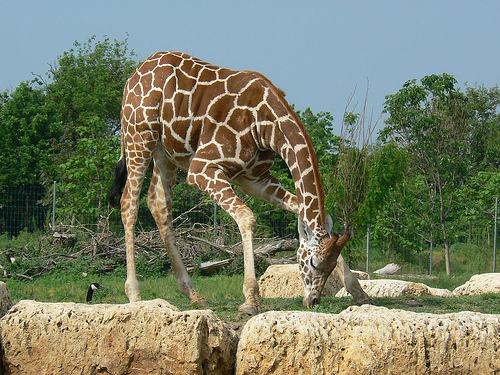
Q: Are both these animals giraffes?
A: No, they are giraffes and birds.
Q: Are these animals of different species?
A: Yes, they are giraffes and birds.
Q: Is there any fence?
A: Yes, there is a fence.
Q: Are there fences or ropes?
A: Yes, there is a fence.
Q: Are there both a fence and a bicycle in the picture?
A: No, there is a fence but no bicycles.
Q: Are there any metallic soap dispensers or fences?
A: Yes, there is a metal fence.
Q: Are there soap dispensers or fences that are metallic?
A: Yes, the fence is metallic.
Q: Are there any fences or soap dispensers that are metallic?
A: Yes, the fence is metallic.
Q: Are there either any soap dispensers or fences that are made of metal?
A: Yes, the fence is made of metal.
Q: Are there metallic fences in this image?
A: Yes, there is a metal fence.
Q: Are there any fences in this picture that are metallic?
A: Yes, there is a fence that is metallic.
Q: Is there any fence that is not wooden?
A: Yes, there is a metallic fence.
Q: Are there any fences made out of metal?
A: Yes, there is a fence that is made of metal.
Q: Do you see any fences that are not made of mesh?
A: Yes, there is a fence that is made of metal.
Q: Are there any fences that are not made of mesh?
A: Yes, there is a fence that is made of metal.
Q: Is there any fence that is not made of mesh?
A: Yes, there is a fence that is made of metal.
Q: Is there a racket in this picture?
A: No, there are no rackets.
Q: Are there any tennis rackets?
A: No, there are no tennis rackets.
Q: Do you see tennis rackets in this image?
A: No, there are no tennis rackets.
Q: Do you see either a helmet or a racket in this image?
A: No, there are no rackets or helmets.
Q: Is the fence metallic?
A: Yes, the fence is metallic.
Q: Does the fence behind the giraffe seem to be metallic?
A: Yes, the fence is metallic.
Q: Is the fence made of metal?
A: Yes, the fence is made of metal.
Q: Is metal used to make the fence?
A: Yes, the fence is made of metal.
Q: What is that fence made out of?
A: The fence is made of metal.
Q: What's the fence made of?
A: The fence is made of metal.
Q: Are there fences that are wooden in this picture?
A: No, there is a fence but it is metallic.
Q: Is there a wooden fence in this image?
A: No, there is a fence but it is metallic.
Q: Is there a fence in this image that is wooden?
A: No, there is a fence but it is metallic.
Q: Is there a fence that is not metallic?
A: No, there is a fence but it is metallic.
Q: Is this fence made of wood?
A: No, the fence is made of metal.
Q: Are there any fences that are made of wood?
A: No, there is a fence but it is made of metal.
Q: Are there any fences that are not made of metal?
A: No, there is a fence but it is made of metal.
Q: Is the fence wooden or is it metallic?
A: The fence is metallic.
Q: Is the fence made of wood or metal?
A: The fence is made of metal.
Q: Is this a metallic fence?
A: Yes, this is a metallic fence.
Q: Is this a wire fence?
A: No, this is a metallic fence.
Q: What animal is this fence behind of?
A: The fence is behind the giraffe.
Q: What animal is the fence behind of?
A: The fence is behind the giraffe.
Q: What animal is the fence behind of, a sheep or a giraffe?
A: The fence is behind a giraffe.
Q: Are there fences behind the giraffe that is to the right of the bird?
A: Yes, there is a fence behind the giraffe.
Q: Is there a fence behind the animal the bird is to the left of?
A: Yes, there is a fence behind the giraffe.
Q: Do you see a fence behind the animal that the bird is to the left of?
A: Yes, there is a fence behind the giraffe.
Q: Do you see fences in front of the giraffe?
A: No, the fence is behind the giraffe.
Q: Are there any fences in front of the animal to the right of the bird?
A: No, the fence is behind the giraffe.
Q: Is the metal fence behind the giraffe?
A: Yes, the fence is behind the giraffe.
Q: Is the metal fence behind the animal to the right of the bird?
A: Yes, the fence is behind the giraffe.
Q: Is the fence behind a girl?
A: No, the fence is behind the giraffe.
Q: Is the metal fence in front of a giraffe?
A: No, the fence is behind a giraffe.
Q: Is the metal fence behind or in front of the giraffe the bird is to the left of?
A: The fence is behind the giraffe.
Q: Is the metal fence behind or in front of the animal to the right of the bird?
A: The fence is behind the giraffe.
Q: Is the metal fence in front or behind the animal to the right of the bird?
A: The fence is behind the giraffe.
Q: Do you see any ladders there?
A: No, there are no ladders.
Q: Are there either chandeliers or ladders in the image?
A: No, there are no ladders or chandeliers.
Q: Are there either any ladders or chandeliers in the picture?
A: No, there are no ladders or chandeliers.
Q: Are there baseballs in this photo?
A: No, there are no baseballs.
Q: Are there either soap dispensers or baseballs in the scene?
A: No, there are no baseballs or soap dispensers.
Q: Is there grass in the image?
A: Yes, there is grass.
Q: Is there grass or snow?
A: Yes, there is grass.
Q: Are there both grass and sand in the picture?
A: No, there is grass but no sand.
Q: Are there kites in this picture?
A: No, there are no kites.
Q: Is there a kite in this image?
A: No, there are no kites.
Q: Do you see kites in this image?
A: No, there are no kites.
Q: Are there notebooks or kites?
A: No, there are no kites or notebooks.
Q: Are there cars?
A: No, there are no cars.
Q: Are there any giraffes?
A: Yes, there is a giraffe.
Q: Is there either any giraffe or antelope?
A: Yes, there is a giraffe.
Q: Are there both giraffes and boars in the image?
A: No, there is a giraffe but no boars.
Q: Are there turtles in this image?
A: No, there are no turtles.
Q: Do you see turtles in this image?
A: No, there are no turtles.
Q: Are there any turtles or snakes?
A: No, there are no turtles or snakes.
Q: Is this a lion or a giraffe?
A: This is a giraffe.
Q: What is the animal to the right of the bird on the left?
A: The animal is a giraffe.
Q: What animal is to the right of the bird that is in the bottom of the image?
A: The animal is a giraffe.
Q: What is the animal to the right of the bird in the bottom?
A: The animal is a giraffe.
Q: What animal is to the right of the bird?
A: The animal is a giraffe.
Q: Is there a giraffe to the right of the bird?
A: Yes, there is a giraffe to the right of the bird.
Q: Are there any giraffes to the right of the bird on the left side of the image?
A: Yes, there is a giraffe to the right of the bird.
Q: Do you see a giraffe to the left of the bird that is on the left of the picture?
A: No, the giraffe is to the right of the bird.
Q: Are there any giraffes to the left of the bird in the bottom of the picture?
A: No, the giraffe is to the right of the bird.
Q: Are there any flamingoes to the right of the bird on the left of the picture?
A: No, there is a giraffe to the right of the bird.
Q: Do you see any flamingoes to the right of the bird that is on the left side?
A: No, there is a giraffe to the right of the bird.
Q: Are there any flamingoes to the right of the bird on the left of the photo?
A: No, there is a giraffe to the right of the bird.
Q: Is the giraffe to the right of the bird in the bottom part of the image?
A: Yes, the giraffe is to the right of the bird.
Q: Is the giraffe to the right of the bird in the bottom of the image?
A: Yes, the giraffe is to the right of the bird.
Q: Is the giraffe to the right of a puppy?
A: No, the giraffe is to the right of the bird.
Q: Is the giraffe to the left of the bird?
A: No, the giraffe is to the right of the bird.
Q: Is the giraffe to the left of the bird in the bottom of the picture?
A: No, the giraffe is to the right of the bird.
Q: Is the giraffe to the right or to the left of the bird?
A: The giraffe is to the right of the bird.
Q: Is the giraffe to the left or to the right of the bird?
A: The giraffe is to the right of the bird.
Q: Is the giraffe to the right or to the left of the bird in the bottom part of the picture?
A: The giraffe is to the right of the bird.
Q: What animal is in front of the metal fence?
A: The giraffe is in front of the fence.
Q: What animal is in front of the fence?
A: The giraffe is in front of the fence.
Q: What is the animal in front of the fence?
A: The animal is a giraffe.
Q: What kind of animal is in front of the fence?
A: The animal is a giraffe.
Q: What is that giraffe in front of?
A: The giraffe is in front of the fence.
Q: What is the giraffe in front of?
A: The giraffe is in front of the fence.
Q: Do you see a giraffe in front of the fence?
A: Yes, there is a giraffe in front of the fence.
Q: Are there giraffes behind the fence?
A: No, the giraffe is in front of the fence.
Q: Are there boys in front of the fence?
A: No, there is a giraffe in front of the fence.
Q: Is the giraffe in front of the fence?
A: Yes, the giraffe is in front of the fence.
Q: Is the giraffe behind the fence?
A: No, the giraffe is in front of the fence.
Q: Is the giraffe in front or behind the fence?
A: The giraffe is in front of the fence.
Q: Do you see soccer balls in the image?
A: No, there are no soccer balls.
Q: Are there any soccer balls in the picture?
A: No, there are no soccer balls.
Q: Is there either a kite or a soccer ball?
A: No, there are no soccer balls or kites.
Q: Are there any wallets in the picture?
A: No, there are no wallets.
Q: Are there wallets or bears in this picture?
A: No, there are no wallets or bears.